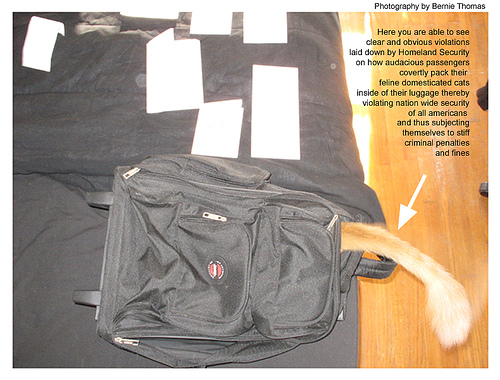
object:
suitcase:
[72, 152, 395, 368]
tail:
[340, 222, 472, 348]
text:
[349, 28, 470, 158]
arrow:
[398, 174, 428, 230]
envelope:
[251, 63, 301, 160]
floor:
[336, 11, 489, 368]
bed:
[13, 12, 360, 370]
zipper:
[122, 167, 141, 180]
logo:
[208, 261, 225, 280]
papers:
[191, 98, 245, 158]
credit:
[374, 2, 485, 11]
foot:
[72, 290, 102, 306]